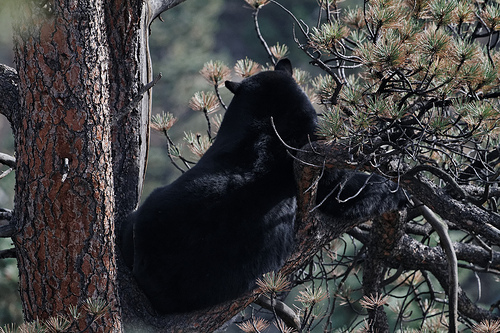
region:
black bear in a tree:
[119, 57, 339, 325]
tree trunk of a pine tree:
[8, 34, 130, 309]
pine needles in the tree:
[365, 28, 442, 72]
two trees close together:
[57, 26, 174, 176]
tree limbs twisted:
[376, 168, 481, 307]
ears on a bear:
[205, 54, 302, 102]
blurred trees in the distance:
[154, 8, 265, 57]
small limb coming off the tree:
[103, 71, 173, 146]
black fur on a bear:
[153, 209, 213, 276]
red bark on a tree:
[40, 129, 82, 234]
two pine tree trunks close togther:
[11, 1, 156, 326]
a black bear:
[128, 57, 313, 317]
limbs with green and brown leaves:
[295, 28, 486, 178]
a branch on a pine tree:
[365, 209, 496, 298]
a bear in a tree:
[98, 51, 433, 327]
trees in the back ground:
[156, 8, 241, 116]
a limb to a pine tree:
[128, 205, 366, 330]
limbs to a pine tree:
[327, 223, 481, 326]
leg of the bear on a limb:
[295, 134, 437, 236]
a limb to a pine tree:
[253, 277, 316, 332]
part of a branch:
[428, 181, 445, 197]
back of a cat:
[211, 235, 225, 242]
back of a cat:
[196, 195, 215, 223]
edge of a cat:
[199, 225, 211, 237]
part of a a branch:
[391, 225, 408, 250]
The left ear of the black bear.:
[220, 80, 242, 90]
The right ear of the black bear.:
[272, 55, 294, 72]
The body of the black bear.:
[94, 120, 302, 297]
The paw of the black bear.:
[400, 172, 430, 200]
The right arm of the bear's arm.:
[264, 178, 374, 242]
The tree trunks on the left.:
[7, 1, 152, 331]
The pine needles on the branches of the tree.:
[152, 3, 494, 235]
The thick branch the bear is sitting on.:
[153, 133, 385, 331]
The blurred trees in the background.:
[70, 5, 464, 135]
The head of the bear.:
[221, 72, 326, 126]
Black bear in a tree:
[146, 51, 358, 330]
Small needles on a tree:
[298, 12, 498, 119]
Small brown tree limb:
[401, 174, 498, 257]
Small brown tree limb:
[259, 289, 303, 331]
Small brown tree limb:
[357, 224, 414, 331]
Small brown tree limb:
[414, 201, 455, 327]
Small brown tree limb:
[110, 74, 184, 144]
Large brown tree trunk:
[13, 17, 104, 322]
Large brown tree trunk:
[106, 3, 153, 232]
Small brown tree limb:
[5, 58, 14, 113]